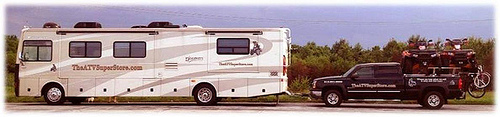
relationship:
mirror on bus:
[14, 49, 29, 72] [18, 32, 283, 101]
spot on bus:
[141, 78, 164, 97] [18, 32, 283, 101]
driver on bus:
[33, 46, 58, 65] [18, 32, 283, 101]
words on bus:
[177, 51, 215, 71] [18, 32, 283, 101]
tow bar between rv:
[284, 84, 312, 103] [14, 22, 294, 104]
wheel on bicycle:
[479, 73, 490, 87] [459, 53, 488, 101]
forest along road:
[296, 36, 443, 74] [250, 98, 499, 115]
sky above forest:
[224, 10, 487, 45] [296, 36, 443, 74]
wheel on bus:
[195, 81, 218, 101] [18, 32, 283, 101]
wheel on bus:
[45, 86, 75, 103] [18, 32, 283, 101]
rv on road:
[43, 24, 237, 97] [250, 98, 499, 115]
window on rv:
[117, 44, 146, 56] [43, 24, 237, 97]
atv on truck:
[401, 45, 480, 77] [311, 68, 462, 105]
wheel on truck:
[324, 90, 342, 107] [311, 68, 462, 105]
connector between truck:
[293, 90, 308, 100] [311, 68, 462, 105]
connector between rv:
[293, 90, 308, 100] [43, 24, 237, 97]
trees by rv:
[288, 44, 392, 74] [43, 24, 237, 97]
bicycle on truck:
[459, 53, 488, 101] [311, 68, 462, 105]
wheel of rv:
[193, 82, 218, 105] [43, 24, 237, 97]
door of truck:
[354, 77, 379, 95] [311, 68, 462, 105]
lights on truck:
[312, 78, 319, 89] [311, 68, 462, 105]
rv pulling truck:
[43, 24, 237, 97] [311, 68, 462, 105]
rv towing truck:
[43, 24, 237, 97] [311, 68, 462, 105]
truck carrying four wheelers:
[311, 68, 462, 105] [399, 40, 487, 80]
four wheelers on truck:
[399, 40, 487, 80] [311, 68, 462, 105]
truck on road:
[311, 68, 462, 105] [250, 98, 499, 115]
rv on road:
[14, 22, 294, 104] [250, 98, 499, 115]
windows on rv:
[55, 36, 161, 65] [43, 24, 237, 97]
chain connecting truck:
[280, 85, 316, 96] [311, 68, 462, 105]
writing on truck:
[345, 78, 394, 95] [311, 68, 462, 105]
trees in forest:
[288, 44, 392, 74] [296, 36, 443, 74]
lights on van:
[12, 20, 126, 33] [43, 24, 237, 97]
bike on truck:
[399, 40, 487, 80] [311, 68, 462, 105]